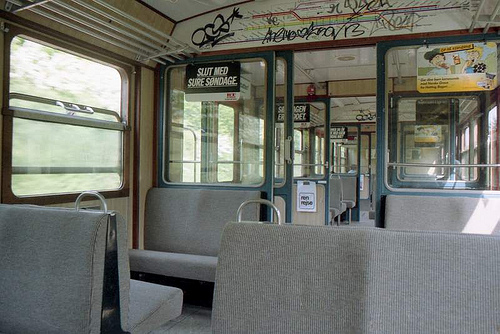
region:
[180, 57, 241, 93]
Black and white sign.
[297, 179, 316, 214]
A black and white paper note on the wall.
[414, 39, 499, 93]
A colorful advertisement on the wall to the right.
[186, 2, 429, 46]
Graffiti tags on on the top center wall.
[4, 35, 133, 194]
An open window to on the nearby left side.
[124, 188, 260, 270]
A gray fabric seating area for passengers.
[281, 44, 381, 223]
Passage way from section of car to other cars of vehicle/train.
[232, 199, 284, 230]
Semi circle silver metallic handle bar.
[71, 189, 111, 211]
A semi circle silver metallic handle bar on the left.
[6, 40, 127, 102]
Sky area and foliage as seen from the window.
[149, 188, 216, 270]
a seat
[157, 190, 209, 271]
the seat is grey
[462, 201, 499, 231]
light on the seat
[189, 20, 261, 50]
tagging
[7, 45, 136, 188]
clear windows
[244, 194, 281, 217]
a handle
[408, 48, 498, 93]
a sticker on the window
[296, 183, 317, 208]
a white sign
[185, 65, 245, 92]
a sign on the window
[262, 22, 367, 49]
tagging on the bus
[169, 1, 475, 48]
map of train station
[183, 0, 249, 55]
graffiti on wall with map on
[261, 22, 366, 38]
graffiti on wall with map on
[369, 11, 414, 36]
graffiti on wall with map on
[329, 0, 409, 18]
graffiti on wall with map on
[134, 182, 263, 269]
gray fabric bench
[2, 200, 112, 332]
gray fabric bench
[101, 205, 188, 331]
gray fabric bench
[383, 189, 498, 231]
gray fabric bench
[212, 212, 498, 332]
gray fabric bench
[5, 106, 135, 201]
Closed window on transit bus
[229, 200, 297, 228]
Handhold on transit bus seat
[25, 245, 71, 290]
Part of gray transit bus seat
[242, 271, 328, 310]
Part of gray transit bus seat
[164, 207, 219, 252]
Part of gray transit bus seat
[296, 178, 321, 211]
Sign on transit bus area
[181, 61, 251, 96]
Sign on transit bus window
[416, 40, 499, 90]
Advertisement on transit bus window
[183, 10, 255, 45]
Graffitti on transit bus area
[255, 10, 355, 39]
Graffitti on transit bus area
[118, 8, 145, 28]
the pipe is white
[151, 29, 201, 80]
the rack is attached to the bus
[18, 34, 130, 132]
the window is open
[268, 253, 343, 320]
the seat is gray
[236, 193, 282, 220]
the handle is silver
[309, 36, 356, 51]
the trim is brown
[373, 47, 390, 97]
the frame is blue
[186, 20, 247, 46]
the garfitte is black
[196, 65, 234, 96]
the words are white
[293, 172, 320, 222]
the sign is white